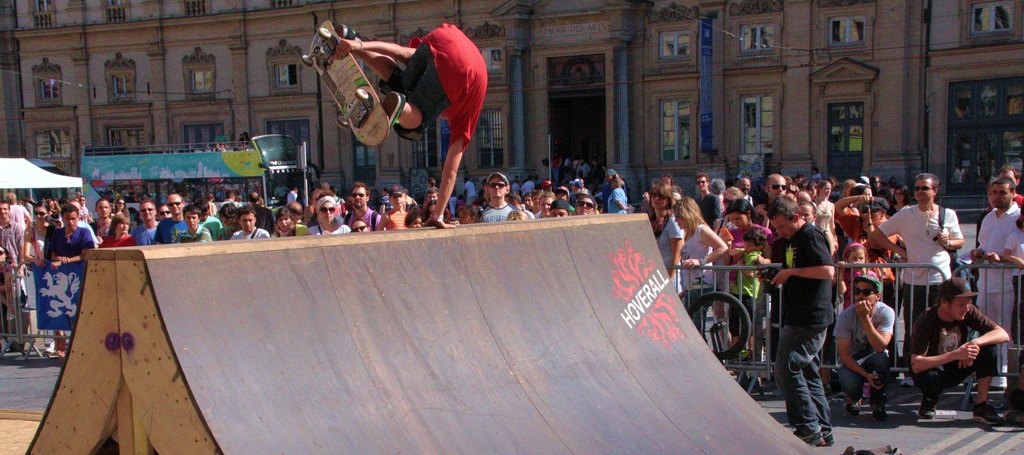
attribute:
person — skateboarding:
[276, 23, 536, 219]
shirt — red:
[298, 17, 486, 233]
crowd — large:
[4, 163, 1022, 398]